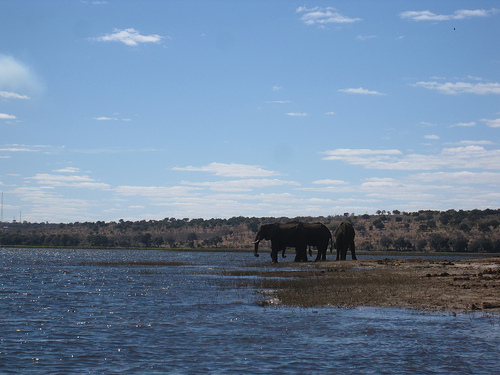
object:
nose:
[252, 236, 260, 259]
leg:
[345, 238, 360, 259]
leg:
[268, 242, 281, 261]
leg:
[315, 245, 322, 257]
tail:
[324, 229, 334, 253]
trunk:
[252, 237, 262, 259]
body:
[264, 220, 313, 264]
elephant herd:
[251, 218, 359, 264]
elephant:
[280, 217, 337, 263]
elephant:
[330, 220, 358, 261]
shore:
[0, 243, 500, 257]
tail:
[306, 238, 315, 258]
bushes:
[0, 231, 80, 247]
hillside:
[0, 207, 500, 253]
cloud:
[338, 85, 384, 99]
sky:
[0, 0, 500, 224]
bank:
[207, 257, 500, 317]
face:
[250, 225, 268, 241]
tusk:
[250, 237, 257, 246]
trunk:
[280, 243, 288, 259]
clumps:
[481, 300, 500, 310]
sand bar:
[248, 255, 500, 311]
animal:
[248, 222, 313, 266]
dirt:
[241, 259, 500, 307]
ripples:
[148, 319, 183, 330]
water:
[0, 247, 500, 373]